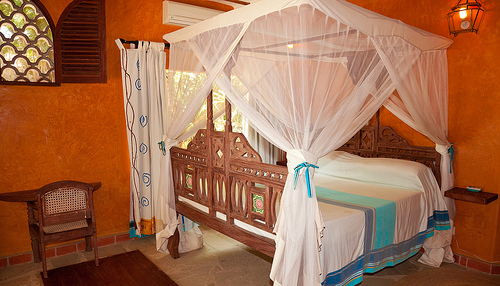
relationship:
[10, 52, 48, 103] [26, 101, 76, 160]
circular piece of glass in window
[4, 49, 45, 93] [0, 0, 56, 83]
circular piece of glass in glass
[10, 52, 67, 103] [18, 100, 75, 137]
circular piece of glass in window